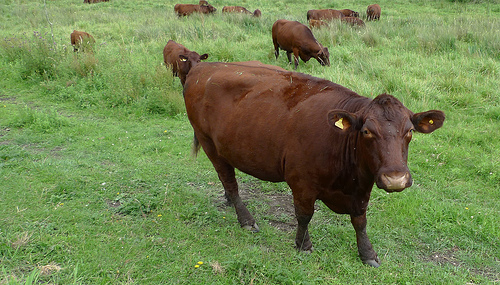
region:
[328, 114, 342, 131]
A yellow tag in the cows ear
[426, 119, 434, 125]
A round yellow tab in the inner ear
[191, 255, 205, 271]
Yellow flower pedals on the ground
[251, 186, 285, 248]
A dirt patch under the cow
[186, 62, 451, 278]
A brown cow in the field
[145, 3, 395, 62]
A herd of brown caddle in the long grass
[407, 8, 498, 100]
The long grass in the field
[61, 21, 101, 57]
A brown cow covered in the tall grass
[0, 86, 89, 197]
Dirt tracks in the grass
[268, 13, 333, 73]
A cow grazes in the field of grass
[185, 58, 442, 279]
brown cow walking down path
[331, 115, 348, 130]
yellow tag on cow's ear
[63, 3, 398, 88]
brown cows grazing in tall grass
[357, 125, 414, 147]
eyes of brown cow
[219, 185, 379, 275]
hooves of brown cow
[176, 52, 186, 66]
yellow tag on ear of cow behind cow on path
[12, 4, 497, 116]
grass cows are grazing on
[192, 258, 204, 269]
yellow flower in the grass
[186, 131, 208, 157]
brown tail of cow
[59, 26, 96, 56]
brown cow partially obscure by tall grass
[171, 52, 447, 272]
a big brown cow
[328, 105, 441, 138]
yellow tags in the cow's ears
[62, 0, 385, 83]
smaller cows in the background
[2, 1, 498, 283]
a grassy field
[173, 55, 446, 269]
a brown cow facing the camera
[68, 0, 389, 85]
cattle grazing in the background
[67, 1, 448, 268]
a herd of cattle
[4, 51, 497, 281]
a grassy path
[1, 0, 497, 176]
taller grass in the background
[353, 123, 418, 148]
two cow eyes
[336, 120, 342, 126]
A yellowish spot in the ear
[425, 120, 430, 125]
A yellow tag in the ear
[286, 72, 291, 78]
A speck of grass on he back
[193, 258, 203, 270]
Yellow flowers in the grass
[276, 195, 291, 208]
A bare patch in the grass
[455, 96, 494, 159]
Green grass on the ground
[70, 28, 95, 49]
Cow half covered by grass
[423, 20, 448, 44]
Tufts of high grass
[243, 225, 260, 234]
A hoof in the grass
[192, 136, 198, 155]
The blackish hairs of the tail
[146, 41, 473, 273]
a big cow up close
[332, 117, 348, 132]
yellow tag in cow's ear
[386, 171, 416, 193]
tan nose of cow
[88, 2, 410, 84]
several cows behind the front cow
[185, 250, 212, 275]
little yellow flowers on the ground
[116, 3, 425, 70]
several cows eating grass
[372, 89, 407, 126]
tuft of hair on top of head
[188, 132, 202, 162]
tip of the cow's tail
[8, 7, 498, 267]
a field of grass with cows grazing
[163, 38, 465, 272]
a large brown cow